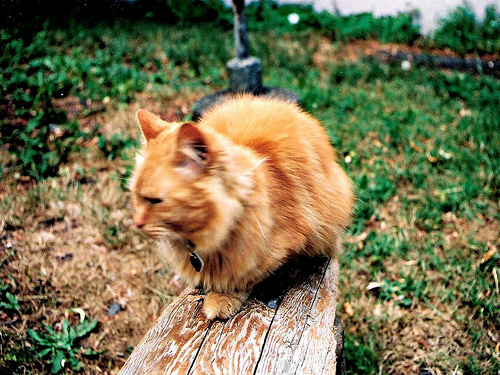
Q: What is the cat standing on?
A: A log.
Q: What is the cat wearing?
A: A collar with a tag.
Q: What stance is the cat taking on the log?
A: Sitting.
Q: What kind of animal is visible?
A: Cat.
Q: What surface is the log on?
A: Grass.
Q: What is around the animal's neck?
A: Collar and tag.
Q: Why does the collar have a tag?
A: Identification.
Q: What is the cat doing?
A: Staring.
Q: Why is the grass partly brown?
A: Dead or dormant areas.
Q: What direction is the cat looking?
A: Left.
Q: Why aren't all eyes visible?
A: Cat's head is turned.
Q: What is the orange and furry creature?
A: Cat.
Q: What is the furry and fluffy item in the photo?
A: Cat.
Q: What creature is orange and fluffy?
A: Cat.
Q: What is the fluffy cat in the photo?
A: Orange.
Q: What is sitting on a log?
A: Yellow cat.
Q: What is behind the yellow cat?
A: Black stand.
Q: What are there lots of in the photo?
A: Plants.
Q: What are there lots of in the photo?
A: Brown plants.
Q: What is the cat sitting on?
A: Log.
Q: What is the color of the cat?
A: Brown.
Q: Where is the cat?
A: Sitting in the wood.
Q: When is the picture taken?
A: Daytime.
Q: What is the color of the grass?
A: Green.